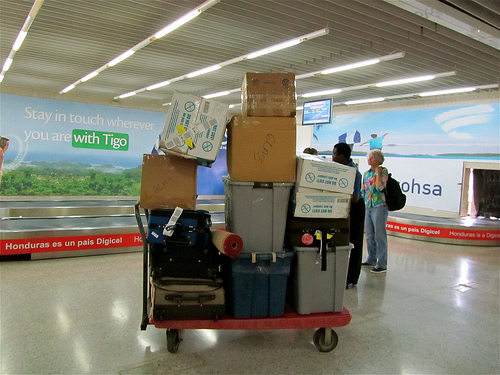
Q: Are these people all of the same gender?
A: No, they are both male and female.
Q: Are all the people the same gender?
A: No, they are both male and female.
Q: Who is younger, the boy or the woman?
A: The boy is younger than the woman.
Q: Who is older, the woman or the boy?
A: The woman is older than the boy.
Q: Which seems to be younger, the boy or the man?
A: The boy is younger than the man.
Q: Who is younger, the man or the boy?
A: The boy is younger than the man.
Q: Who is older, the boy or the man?
A: The man is older than the boy.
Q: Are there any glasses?
A: No, there are no glasses.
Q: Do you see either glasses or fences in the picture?
A: No, there are no glasses or fences.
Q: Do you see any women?
A: Yes, there is a woman.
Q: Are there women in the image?
A: Yes, there is a woman.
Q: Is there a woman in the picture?
A: Yes, there is a woman.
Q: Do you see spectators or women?
A: Yes, there is a woman.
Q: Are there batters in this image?
A: No, there are no batters.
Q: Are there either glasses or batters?
A: No, there are no batters or glasses.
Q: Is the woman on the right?
A: Yes, the woman is on the right of the image.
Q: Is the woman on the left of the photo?
A: No, the woman is on the right of the image.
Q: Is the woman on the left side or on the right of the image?
A: The woman is on the right of the image.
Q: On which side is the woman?
A: The woman is on the right of the image.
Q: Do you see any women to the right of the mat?
A: Yes, there is a woman to the right of the mat.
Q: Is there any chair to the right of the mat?
A: No, there is a woman to the right of the mat.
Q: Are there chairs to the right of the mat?
A: No, there is a woman to the right of the mat.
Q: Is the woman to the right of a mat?
A: Yes, the woman is to the right of a mat.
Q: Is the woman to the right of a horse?
A: No, the woman is to the right of a mat.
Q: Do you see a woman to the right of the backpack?
A: No, the woman is to the left of the backpack.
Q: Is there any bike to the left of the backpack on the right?
A: No, there is a woman to the left of the backpack.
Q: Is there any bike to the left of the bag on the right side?
A: No, there is a woman to the left of the backpack.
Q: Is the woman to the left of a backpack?
A: Yes, the woman is to the left of a backpack.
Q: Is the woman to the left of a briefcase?
A: No, the woman is to the left of a backpack.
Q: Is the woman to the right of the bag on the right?
A: No, the woman is to the left of the backpack.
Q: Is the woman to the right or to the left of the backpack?
A: The woman is to the left of the backpack.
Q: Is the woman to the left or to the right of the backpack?
A: The woman is to the left of the backpack.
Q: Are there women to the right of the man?
A: Yes, there is a woman to the right of the man.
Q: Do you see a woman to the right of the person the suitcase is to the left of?
A: Yes, there is a woman to the right of the man.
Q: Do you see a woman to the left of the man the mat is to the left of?
A: No, the woman is to the right of the man.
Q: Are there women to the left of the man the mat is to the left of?
A: No, the woman is to the right of the man.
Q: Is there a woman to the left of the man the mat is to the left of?
A: No, the woman is to the right of the man.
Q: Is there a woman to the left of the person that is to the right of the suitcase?
A: No, the woman is to the right of the man.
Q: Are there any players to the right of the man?
A: No, there is a woman to the right of the man.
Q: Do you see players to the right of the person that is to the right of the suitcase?
A: No, there is a woman to the right of the man.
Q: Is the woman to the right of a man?
A: Yes, the woman is to the right of a man.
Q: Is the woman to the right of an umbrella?
A: No, the woman is to the right of a man.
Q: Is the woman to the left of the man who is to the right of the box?
A: No, the woman is to the right of the man.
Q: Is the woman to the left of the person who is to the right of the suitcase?
A: No, the woman is to the right of the man.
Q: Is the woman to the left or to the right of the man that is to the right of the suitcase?
A: The woman is to the right of the man.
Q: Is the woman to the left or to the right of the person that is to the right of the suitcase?
A: The woman is to the right of the man.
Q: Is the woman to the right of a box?
A: Yes, the woman is to the right of a box.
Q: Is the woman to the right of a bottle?
A: No, the woman is to the right of a box.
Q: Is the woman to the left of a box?
A: No, the woman is to the right of a box.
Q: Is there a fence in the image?
A: No, there are no fences.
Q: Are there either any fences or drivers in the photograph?
A: No, there are no fences or drivers.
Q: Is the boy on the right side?
A: Yes, the boy is on the right of the image.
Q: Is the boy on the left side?
A: No, the boy is on the right of the image.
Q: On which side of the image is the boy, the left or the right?
A: The boy is on the right of the image.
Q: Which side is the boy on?
A: The boy is on the right of the image.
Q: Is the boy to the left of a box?
A: No, the boy is to the right of a box.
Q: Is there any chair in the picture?
A: No, there are no chairs.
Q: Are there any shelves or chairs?
A: No, there are no chairs or shelves.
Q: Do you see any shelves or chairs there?
A: No, there are no chairs or shelves.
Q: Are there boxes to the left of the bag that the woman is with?
A: Yes, there is a box to the left of the backpack.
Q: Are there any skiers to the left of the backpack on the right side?
A: No, there is a box to the left of the backpack.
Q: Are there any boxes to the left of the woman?
A: Yes, there is a box to the left of the woman.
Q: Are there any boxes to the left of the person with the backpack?
A: Yes, there is a box to the left of the woman.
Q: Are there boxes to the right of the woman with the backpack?
A: No, the box is to the left of the woman.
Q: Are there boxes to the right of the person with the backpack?
A: No, the box is to the left of the woman.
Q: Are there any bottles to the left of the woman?
A: No, there is a box to the left of the woman.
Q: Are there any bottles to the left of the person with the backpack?
A: No, there is a box to the left of the woman.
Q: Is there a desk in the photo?
A: No, there are no desks.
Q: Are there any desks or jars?
A: No, there are no desks or jars.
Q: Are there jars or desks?
A: No, there are no desks or jars.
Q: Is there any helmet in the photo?
A: No, there are no helmets.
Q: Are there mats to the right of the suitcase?
A: Yes, there is a mat to the right of the suitcase.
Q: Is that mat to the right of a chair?
A: No, the mat is to the right of the suitcase.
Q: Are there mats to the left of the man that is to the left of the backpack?
A: Yes, there is a mat to the left of the man.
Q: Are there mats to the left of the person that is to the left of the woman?
A: Yes, there is a mat to the left of the man.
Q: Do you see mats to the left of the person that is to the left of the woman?
A: Yes, there is a mat to the left of the man.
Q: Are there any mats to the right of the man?
A: No, the mat is to the left of the man.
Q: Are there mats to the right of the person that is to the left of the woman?
A: No, the mat is to the left of the man.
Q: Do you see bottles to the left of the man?
A: No, there is a mat to the left of the man.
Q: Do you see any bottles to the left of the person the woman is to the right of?
A: No, there is a mat to the left of the man.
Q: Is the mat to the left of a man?
A: Yes, the mat is to the left of a man.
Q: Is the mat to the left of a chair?
A: No, the mat is to the left of a man.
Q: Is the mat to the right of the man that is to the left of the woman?
A: No, the mat is to the left of the man.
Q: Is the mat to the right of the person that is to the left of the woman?
A: No, the mat is to the left of the man.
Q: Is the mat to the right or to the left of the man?
A: The mat is to the left of the man.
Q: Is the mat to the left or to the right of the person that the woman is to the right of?
A: The mat is to the left of the man.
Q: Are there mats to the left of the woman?
A: Yes, there is a mat to the left of the woman.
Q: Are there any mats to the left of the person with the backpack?
A: Yes, there is a mat to the left of the woman.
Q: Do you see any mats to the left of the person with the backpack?
A: Yes, there is a mat to the left of the woman.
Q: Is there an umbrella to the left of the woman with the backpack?
A: No, there is a mat to the left of the woman.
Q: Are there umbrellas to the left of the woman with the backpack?
A: No, there is a mat to the left of the woman.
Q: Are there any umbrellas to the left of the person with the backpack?
A: No, there is a mat to the left of the woman.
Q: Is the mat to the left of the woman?
A: Yes, the mat is to the left of the woman.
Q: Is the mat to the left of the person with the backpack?
A: Yes, the mat is to the left of the woman.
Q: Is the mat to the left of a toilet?
A: No, the mat is to the left of the woman.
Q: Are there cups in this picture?
A: No, there are no cups.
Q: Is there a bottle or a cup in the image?
A: No, there are no cups or bottles.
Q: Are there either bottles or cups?
A: No, there are no cups or bottles.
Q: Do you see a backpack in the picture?
A: Yes, there is a backpack.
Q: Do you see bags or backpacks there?
A: Yes, there is a backpack.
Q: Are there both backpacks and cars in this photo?
A: No, there is a backpack but no cars.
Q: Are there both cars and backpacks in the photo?
A: No, there is a backpack but no cars.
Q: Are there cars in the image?
A: No, there are no cars.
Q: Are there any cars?
A: No, there are no cars.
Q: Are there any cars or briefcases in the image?
A: No, there are no cars or briefcases.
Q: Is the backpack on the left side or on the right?
A: The backpack is on the right of the image.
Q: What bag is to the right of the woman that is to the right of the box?
A: The bag is a backpack.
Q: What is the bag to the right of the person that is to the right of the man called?
A: The bag is a backpack.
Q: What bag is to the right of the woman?
A: The bag is a backpack.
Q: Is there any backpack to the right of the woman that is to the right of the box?
A: Yes, there is a backpack to the right of the woman.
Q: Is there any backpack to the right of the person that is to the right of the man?
A: Yes, there is a backpack to the right of the woman.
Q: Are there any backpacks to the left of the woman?
A: No, the backpack is to the right of the woman.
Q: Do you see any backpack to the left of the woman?
A: No, the backpack is to the right of the woman.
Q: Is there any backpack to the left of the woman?
A: No, the backpack is to the right of the woman.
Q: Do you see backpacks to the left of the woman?
A: No, the backpack is to the right of the woman.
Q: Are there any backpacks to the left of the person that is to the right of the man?
A: No, the backpack is to the right of the woman.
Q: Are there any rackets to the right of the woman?
A: No, there is a backpack to the right of the woman.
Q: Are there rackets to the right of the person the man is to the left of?
A: No, there is a backpack to the right of the woman.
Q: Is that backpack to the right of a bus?
A: No, the backpack is to the right of a woman.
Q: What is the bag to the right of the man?
A: The bag is a backpack.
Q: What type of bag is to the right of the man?
A: The bag is a backpack.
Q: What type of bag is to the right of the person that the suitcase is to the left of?
A: The bag is a backpack.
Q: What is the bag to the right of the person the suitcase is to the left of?
A: The bag is a backpack.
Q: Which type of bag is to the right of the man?
A: The bag is a backpack.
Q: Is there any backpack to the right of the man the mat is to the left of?
A: Yes, there is a backpack to the right of the man.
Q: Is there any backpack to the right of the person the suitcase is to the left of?
A: Yes, there is a backpack to the right of the man.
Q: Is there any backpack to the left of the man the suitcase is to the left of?
A: No, the backpack is to the right of the man.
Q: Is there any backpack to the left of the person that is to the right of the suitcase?
A: No, the backpack is to the right of the man.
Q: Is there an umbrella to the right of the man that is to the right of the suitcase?
A: No, there is a backpack to the right of the man.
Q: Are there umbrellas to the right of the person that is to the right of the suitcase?
A: No, there is a backpack to the right of the man.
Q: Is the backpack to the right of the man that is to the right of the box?
A: Yes, the backpack is to the right of the man.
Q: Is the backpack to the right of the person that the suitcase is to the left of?
A: Yes, the backpack is to the right of the man.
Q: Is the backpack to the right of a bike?
A: No, the backpack is to the right of the man.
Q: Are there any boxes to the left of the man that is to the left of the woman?
A: Yes, there is a box to the left of the man.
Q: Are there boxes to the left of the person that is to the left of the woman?
A: Yes, there is a box to the left of the man.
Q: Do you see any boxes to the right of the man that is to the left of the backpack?
A: No, the box is to the left of the man.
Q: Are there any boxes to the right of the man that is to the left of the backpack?
A: No, the box is to the left of the man.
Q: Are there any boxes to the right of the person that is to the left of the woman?
A: No, the box is to the left of the man.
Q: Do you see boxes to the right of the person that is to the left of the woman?
A: No, the box is to the left of the man.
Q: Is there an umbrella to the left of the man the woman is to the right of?
A: No, there is a box to the left of the man.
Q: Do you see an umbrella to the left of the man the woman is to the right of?
A: No, there is a box to the left of the man.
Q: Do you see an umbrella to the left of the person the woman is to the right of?
A: No, there is a box to the left of the man.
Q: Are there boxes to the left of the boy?
A: Yes, there is a box to the left of the boy.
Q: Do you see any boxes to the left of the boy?
A: Yes, there is a box to the left of the boy.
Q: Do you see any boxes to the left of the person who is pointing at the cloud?
A: Yes, there is a box to the left of the boy.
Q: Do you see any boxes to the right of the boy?
A: No, the box is to the left of the boy.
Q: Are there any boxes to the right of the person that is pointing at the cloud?
A: No, the box is to the left of the boy.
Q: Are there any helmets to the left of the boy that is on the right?
A: No, there is a box to the left of the boy.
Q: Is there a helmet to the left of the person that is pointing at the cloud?
A: No, there is a box to the left of the boy.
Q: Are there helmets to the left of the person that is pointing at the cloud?
A: No, there is a box to the left of the boy.